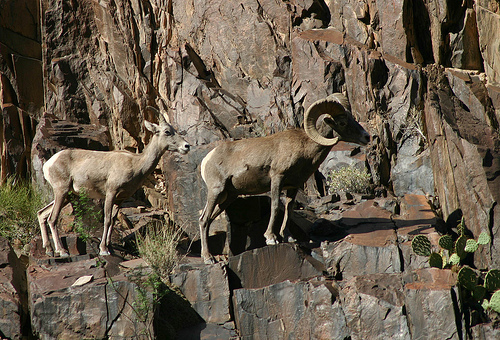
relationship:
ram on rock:
[196, 94, 379, 254] [34, 249, 385, 339]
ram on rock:
[28, 105, 191, 252] [34, 249, 385, 339]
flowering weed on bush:
[325, 164, 373, 195] [320, 160, 382, 199]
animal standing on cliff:
[197, 92, 370, 265] [0, 0, 499, 340]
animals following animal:
[37, 105, 191, 256] [197, 92, 370, 265]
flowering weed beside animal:
[325, 164, 373, 195] [197, 92, 370, 265]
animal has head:
[197, 92, 370, 265] [302, 87, 371, 148]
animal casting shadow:
[197, 92, 370, 265] [312, 207, 452, 268]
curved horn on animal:
[300, 86, 352, 148] [187, 87, 377, 267]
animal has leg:
[187, 87, 377, 267] [261, 171, 283, 247]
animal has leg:
[197, 92, 370, 265] [280, 188, 296, 245]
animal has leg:
[197, 92, 370, 265] [196, 191, 221, 266]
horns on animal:
[297, 93, 359, 168] [195, 92, 375, 247]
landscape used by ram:
[5, 1, 497, 338] [196, 94, 373, 266]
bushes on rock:
[4, 179, 34, 239] [3, 234, 93, 334]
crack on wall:
[426, 81, 467, 214] [41, 8, 491, 183]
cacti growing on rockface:
[410, 202, 499, 313] [0, 1, 499, 336]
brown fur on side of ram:
[222, 141, 295, 165] [196, 94, 373, 266]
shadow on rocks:
[291, 209, 463, 246] [0, 3, 499, 338]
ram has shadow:
[196, 94, 373, 266] [291, 209, 463, 246]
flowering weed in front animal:
[325, 164, 382, 199] [197, 92, 370, 265]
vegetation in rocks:
[130, 215, 197, 322] [25, 252, 240, 337]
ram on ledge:
[28, 92, 212, 269] [3, 225, 462, 295]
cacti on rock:
[410, 207, 500, 327] [358, 4, 477, 310]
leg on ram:
[105, 197, 120, 253] [35, 100, 190, 260]